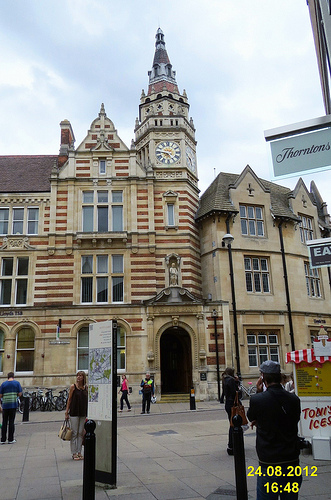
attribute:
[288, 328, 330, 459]
stand — red, kiosk, white, ice cream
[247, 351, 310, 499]
man — expanitory, talking, walking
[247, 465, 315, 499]
stamp — yellow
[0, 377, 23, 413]
shirt — blue, striped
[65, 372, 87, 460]
woman — walking, confused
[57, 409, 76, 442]
purse — brown, tan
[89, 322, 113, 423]
map — directional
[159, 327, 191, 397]
door — tall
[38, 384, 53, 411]
bike — parked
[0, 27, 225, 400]
building — brick, tall, old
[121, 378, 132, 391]
top — pink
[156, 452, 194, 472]
stone — grey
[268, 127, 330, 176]
sign — advertisement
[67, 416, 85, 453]
pants — gray